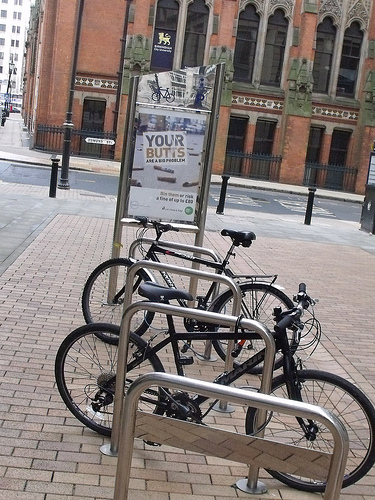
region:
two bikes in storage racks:
[91, 230, 370, 480]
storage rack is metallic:
[119, 300, 264, 493]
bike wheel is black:
[252, 365, 367, 495]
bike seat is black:
[225, 226, 260, 253]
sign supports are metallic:
[102, 122, 220, 295]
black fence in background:
[44, 126, 356, 194]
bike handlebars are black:
[121, 207, 170, 230]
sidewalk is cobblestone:
[32, 210, 371, 498]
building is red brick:
[41, 62, 369, 186]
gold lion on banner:
[159, 25, 171, 48]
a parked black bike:
[82, 216, 304, 366]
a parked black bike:
[55, 282, 371, 486]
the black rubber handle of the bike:
[136, 216, 148, 224]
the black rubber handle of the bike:
[166, 221, 179, 233]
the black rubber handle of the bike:
[276, 311, 292, 334]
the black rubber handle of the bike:
[298, 281, 305, 293]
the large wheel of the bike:
[245, 364, 374, 491]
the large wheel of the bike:
[55, 322, 168, 442]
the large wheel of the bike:
[80, 255, 157, 340]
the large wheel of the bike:
[211, 273, 301, 367]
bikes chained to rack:
[86, 141, 351, 452]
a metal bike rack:
[112, 217, 354, 484]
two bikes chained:
[118, 196, 339, 469]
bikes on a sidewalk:
[102, 200, 323, 497]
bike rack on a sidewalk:
[97, 208, 350, 489]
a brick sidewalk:
[7, 181, 90, 313]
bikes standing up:
[95, 203, 367, 440]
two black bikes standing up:
[99, 205, 329, 462]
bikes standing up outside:
[122, 210, 330, 441]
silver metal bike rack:
[47, 206, 350, 499]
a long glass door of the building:
[77, 92, 108, 154]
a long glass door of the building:
[226, 112, 246, 173]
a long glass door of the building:
[305, 122, 323, 182]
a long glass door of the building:
[327, 123, 354, 185]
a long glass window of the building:
[152, 5, 177, 69]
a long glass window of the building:
[181, 1, 207, 78]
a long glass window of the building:
[235, 6, 261, 83]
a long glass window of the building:
[313, 14, 333, 97]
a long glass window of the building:
[340, 18, 363, 97]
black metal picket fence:
[226, 148, 283, 180]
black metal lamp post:
[60, 0, 81, 190]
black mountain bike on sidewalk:
[49, 283, 373, 490]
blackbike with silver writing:
[83, 217, 299, 359]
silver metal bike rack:
[115, 374, 348, 498]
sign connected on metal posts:
[127, 62, 218, 224]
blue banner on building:
[152, 28, 172, 70]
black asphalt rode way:
[0, 158, 360, 222]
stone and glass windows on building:
[238, 0, 295, 93]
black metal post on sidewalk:
[304, 186, 315, 226]